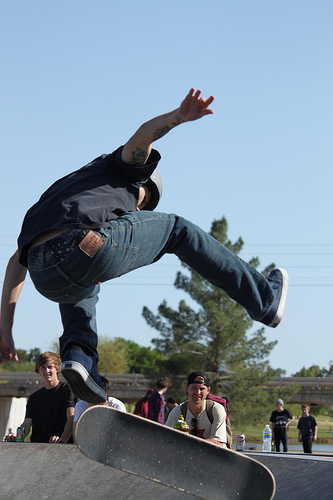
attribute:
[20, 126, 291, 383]
man — skating, white, high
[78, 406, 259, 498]
skateboard — black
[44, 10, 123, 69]
sky — blue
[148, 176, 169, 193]
cap — black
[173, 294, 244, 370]
tree — far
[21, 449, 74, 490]
ramp — close, black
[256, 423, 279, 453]
bottle — close, clear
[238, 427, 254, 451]
soda — clear